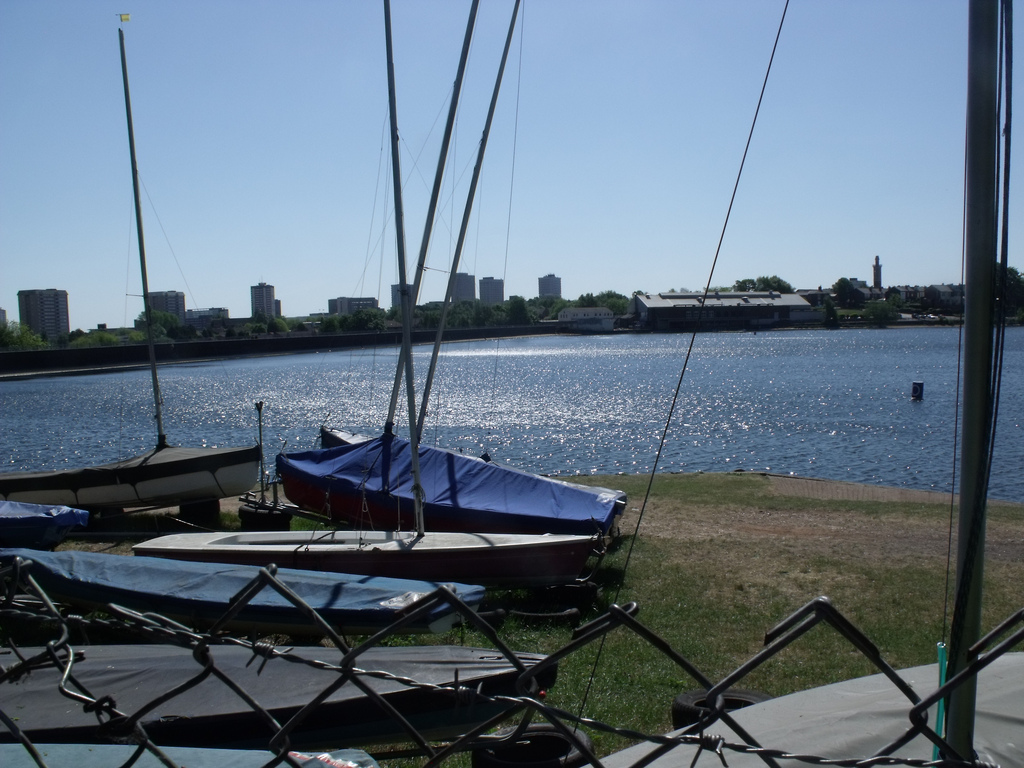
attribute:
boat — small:
[280, 424, 631, 583]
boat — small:
[5, 435, 268, 509]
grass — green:
[438, 467, 1021, 744]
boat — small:
[131, 519, 612, 578]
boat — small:
[18, 549, 489, 639]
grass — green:
[492, 467, 1020, 765]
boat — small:
[5, 633, 560, 754]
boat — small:
[0, 732, 390, 767]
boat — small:
[595, 644, 1022, 766]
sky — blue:
[2, 1, 1021, 334]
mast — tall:
[113, 10, 171, 456]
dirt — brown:
[615, 487, 1021, 571]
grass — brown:
[5, 478, 1023, 766]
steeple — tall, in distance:
[868, 250, 887, 290]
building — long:
[631, 288, 818, 327]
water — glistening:
[0, 323, 1022, 502]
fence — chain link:
[2, 553, 1014, 766]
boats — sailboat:
[0, 425, 1016, 764]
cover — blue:
[280, 433, 623, 522]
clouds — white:
[177, 76, 305, 219]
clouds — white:
[555, 80, 676, 202]